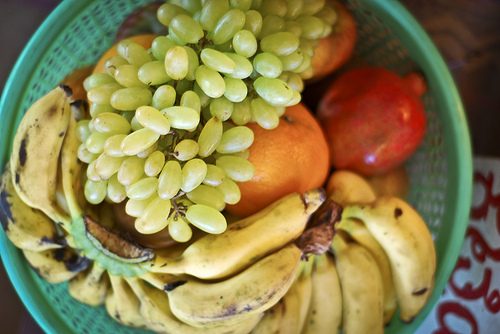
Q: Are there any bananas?
A: Yes, there are bananas.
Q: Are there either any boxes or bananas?
A: Yes, there are bananas.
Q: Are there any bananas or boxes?
A: Yes, there are bananas.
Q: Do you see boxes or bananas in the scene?
A: Yes, there are bananas.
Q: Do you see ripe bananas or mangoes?
A: Yes, there are ripe bananas.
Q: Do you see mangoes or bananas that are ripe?
A: Yes, the bananas are ripe.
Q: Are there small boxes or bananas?
A: Yes, there are small bananas.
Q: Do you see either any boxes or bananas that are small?
A: Yes, the bananas are small.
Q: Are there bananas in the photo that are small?
A: Yes, there are small bananas.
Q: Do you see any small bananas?
A: Yes, there are small bananas.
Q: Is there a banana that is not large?
A: Yes, there are small bananas.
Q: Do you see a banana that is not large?
A: Yes, there are small bananas.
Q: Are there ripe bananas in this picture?
A: Yes, there are ripe bananas.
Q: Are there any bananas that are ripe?
A: Yes, there are bananas that are ripe.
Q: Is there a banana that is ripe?
A: Yes, there are bananas that are ripe.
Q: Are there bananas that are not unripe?
A: Yes, there are ripe bananas.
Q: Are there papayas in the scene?
A: No, there are no papayas.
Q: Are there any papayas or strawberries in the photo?
A: No, there are no papayas or strawberries.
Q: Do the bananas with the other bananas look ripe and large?
A: No, the bananas are ripe but small.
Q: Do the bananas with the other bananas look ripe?
A: Yes, the bananas are ripe.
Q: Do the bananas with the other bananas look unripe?
A: No, the bananas are ripe.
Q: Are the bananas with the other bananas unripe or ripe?
A: The bananas are ripe.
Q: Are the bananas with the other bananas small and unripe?
A: No, the bananas are small but ripe.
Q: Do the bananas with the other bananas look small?
A: Yes, the bananas are small.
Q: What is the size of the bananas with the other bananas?
A: The bananas are small.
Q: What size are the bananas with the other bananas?
A: The bananas are small.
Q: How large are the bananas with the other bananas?
A: The bananas are small.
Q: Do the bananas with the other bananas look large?
A: No, the bananas are small.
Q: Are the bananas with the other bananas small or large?
A: The bananas are small.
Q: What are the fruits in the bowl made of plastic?
A: The fruits are bananas.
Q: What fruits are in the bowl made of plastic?
A: The fruits are bananas.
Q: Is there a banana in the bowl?
A: Yes, there are bananas in the bowl.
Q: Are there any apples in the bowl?
A: No, there are bananas in the bowl.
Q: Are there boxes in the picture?
A: No, there are no boxes.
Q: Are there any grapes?
A: Yes, there are grapes.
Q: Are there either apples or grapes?
A: Yes, there are grapes.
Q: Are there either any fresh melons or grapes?
A: Yes, there are fresh grapes.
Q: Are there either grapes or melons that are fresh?
A: Yes, the grapes are fresh.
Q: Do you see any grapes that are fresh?
A: Yes, there are fresh grapes.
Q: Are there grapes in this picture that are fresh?
A: Yes, there are grapes that are fresh.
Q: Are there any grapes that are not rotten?
A: Yes, there are fresh grapes.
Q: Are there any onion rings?
A: No, there are no onion rings.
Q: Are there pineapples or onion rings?
A: No, there are no onion rings or pineapples.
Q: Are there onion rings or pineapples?
A: No, there are no onion rings or pineapples.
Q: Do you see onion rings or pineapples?
A: No, there are no onion rings or pineapples.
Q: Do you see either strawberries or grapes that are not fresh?
A: No, there are grapes but they are fresh.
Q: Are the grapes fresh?
A: Yes, the grapes are fresh.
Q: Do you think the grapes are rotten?
A: No, the grapes are fresh.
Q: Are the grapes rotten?
A: No, the grapes are fresh.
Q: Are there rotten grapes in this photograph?
A: No, there are grapes but they are fresh.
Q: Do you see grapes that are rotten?
A: No, there are grapes but they are fresh.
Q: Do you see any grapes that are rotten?
A: No, there are grapes but they are fresh.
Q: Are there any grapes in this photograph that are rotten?
A: No, there are grapes but they are fresh.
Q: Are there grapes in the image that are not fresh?
A: No, there are grapes but they are fresh.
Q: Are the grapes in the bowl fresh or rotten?
A: The grapes are fresh.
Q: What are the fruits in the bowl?
A: The fruits are grapes.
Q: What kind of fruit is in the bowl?
A: The fruits are grapes.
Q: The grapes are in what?
A: The grapes are in the bowl.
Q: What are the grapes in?
A: The grapes are in the bowl.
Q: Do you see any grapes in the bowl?
A: Yes, there are grapes in the bowl.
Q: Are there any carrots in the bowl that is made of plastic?
A: No, there are grapes in the bowl.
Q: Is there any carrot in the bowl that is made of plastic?
A: No, there are grapes in the bowl.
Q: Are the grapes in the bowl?
A: Yes, the grapes are in the bowl.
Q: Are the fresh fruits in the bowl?
A: Yes, the grapes are in the bowl.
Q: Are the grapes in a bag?
A: No, the grapes are in the bowl.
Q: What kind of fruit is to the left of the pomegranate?
A: The fruits are grapes.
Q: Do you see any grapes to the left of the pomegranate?
A: Yes, there are grapes to the left of the pomegranate.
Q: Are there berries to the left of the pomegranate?
A: No, there are grapes to the left of the pomegranate.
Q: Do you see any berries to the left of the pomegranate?
A: No, there are grapes to the left of the pomegranate.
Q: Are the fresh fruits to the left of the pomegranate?
A: Yes, the grapes are to the left of the pomegranate.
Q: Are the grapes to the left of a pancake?
A: No, the grapes are to the left of the pomegranate.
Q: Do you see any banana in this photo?
A: Yes, there are bananas.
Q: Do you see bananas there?
A: Yes, there are bananas.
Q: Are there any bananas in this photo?
A: Yes, there are bananas.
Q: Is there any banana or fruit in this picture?
A: Yes, there are bananas.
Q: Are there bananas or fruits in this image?
A: Yes, there are bananas.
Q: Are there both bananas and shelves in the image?
A: No, there are bananas but no shelves.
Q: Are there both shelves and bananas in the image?
A: No, there are bananas but no shelves.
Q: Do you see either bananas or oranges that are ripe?
A: Yes, the bananas are ripe.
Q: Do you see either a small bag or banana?
A: Yes, there are small bananas.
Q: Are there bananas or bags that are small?
A: Yes, the bananas are small.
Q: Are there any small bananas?
A: Yes, there are small bananas.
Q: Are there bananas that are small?
A: Yes, there are bananas that are small.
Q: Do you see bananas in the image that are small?
A: Yes, there are bananas that are small.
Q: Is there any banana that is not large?
A: Yes, there are small bananas.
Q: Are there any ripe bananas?
A: Yes, there are ripe bananas.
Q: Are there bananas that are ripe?
A: Yes, there are bananas that are ripe.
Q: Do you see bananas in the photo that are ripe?
A: Yes, there are bananas that are ripe.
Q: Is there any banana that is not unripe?
A: Yes, there are ripe bananas.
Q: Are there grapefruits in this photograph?
A: No, there are no grapefruits.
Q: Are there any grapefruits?
A: No, there are no grapefruits.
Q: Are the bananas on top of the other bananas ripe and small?
A: Yes, the bananas are ripe and small.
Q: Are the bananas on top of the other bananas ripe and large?
A: No, the bananas are ripe but small.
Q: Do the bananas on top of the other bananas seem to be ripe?
A: Yes, the bananas are ripe.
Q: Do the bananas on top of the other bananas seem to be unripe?
A: No, the bananas are ripe.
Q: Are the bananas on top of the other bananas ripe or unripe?
A: The bananas are ripe.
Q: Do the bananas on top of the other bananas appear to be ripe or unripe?
A: The bananas are ripe.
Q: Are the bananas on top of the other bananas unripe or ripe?
A: The bananas are ripe.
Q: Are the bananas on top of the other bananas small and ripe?
A: Yes, the bananas are small and ripe.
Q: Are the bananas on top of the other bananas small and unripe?
A: No, the bananas are small but ripe.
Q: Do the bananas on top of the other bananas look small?
A: Yes, the bananas are small.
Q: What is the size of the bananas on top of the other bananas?
A: The bananas are small.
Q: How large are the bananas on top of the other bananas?
A: The bananas are small.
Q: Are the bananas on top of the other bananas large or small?
A: The bananas are small.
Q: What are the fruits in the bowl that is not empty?
A: The fruits are bananas.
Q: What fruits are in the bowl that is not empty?
A: The fruits are bananas.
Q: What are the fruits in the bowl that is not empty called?
A: The fruits are bananas.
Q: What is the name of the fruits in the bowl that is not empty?
A: The fruits are bananas.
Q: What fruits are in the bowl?
A: The fruits are bananas.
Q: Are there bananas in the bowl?
A: Yes, there are bananas in the bowl.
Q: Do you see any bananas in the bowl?
A: Yes, there are bananas in the bowl.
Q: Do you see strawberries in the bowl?
A: No, there are bananas in the bowl.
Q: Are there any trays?
A: No, there are no trays.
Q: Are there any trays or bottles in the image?
A: No, there are no trays or bottles.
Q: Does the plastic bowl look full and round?
A: Yes, the bowl is full and round.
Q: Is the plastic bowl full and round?
A: Yes, the bowl is full and round.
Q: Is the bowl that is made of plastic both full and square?
A: No, the bowl is full but round.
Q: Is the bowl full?
A: Yes, the bowl is full.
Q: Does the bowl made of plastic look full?
A: Yes, the bowl is full.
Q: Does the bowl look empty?
A: No, the bowl is full.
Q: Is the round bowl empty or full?
A: The bowl is full.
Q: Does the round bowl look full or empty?
A: The bowl is full.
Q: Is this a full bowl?
A: Yes, this is a full bowl.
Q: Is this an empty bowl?
A: No, this is a full bowl.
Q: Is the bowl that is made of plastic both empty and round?
A: No, the bowl is round but full.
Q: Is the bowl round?
A: Yes, the bowl is round.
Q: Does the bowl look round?
A: Yes, the bowl is round.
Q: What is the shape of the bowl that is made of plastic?
A: The bowl is round.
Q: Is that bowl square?
A: No, the bowl is round.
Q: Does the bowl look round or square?
A: The bowl is round.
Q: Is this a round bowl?
A: Yes, this is a round bowl.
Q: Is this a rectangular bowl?
A: No, this is a round bowl.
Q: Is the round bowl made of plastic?
A: Yes, the bowl is made of plastic.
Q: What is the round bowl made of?
A: The bowl is made of plastic.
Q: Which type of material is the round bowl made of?
A: The bowl is made of plastic.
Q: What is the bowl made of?
A: The bowl is made of plastic.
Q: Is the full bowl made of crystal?
A: No, the bowl is made of plastic.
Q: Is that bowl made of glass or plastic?
A: The bowl is made of plastic.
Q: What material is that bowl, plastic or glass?
A: The bowl is made of plastic.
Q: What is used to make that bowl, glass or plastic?
A: The bowl is made of plastic.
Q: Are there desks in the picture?
A: No, there are no desks.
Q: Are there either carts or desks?
A: No, there are no desks or carts.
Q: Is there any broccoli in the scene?
A: No, there is no broccoli.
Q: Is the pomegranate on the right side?
A: Yes, the pomegranate is on the right of the image.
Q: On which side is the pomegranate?
A: The pomegranate is on the right of the image.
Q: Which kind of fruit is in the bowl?
A: The fruit is a pomegranate.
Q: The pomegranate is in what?
A: The pomegranate is in the bowl.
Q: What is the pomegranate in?
A: The pomegranate is in the bowl.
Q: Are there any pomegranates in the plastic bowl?
A: Yes, there is a pomegranate in the bowl.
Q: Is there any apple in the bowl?
A: No, there is a pomegranate in the bowl.